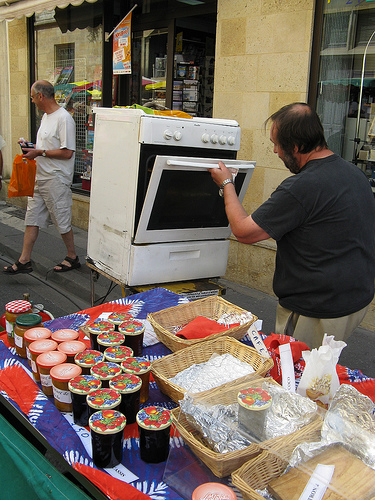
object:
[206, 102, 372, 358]
man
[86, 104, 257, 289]
oven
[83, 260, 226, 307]
cart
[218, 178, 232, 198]
watch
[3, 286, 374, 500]
table cloth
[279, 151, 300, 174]
beard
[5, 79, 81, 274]
person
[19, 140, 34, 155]
wallet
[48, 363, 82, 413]
jar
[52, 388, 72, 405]
label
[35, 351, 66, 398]
jar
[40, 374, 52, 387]
label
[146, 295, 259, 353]
basket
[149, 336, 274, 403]
basket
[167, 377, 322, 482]
basket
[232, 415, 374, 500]
basket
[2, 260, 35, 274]
sandal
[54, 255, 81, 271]
sandal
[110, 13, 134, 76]
banner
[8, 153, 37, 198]
bag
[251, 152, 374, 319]
shirt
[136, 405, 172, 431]
lid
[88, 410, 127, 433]
lid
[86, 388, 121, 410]
lid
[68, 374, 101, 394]
lid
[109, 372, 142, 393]
lid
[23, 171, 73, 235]
pants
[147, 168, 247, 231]
window